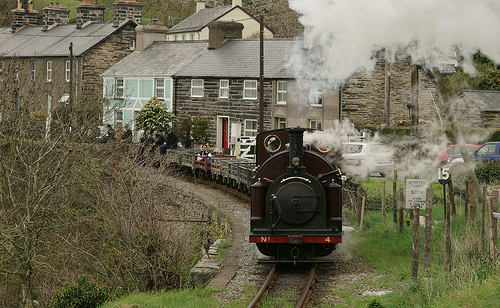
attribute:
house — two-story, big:
[175, 15, 340, 170]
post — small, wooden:
[414, 199, 421, 278]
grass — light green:
[69, 282, 256, 305]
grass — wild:
[135, 292, 194, 306]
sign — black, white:
[403, 175, 428, 216]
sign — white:
[399, 174, 430, 277]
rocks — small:
[237, 260, 249, 284]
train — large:
[164, 130, 345, 257]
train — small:
[232, 134, 364, 255]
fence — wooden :
[346, 164, 498, 288]